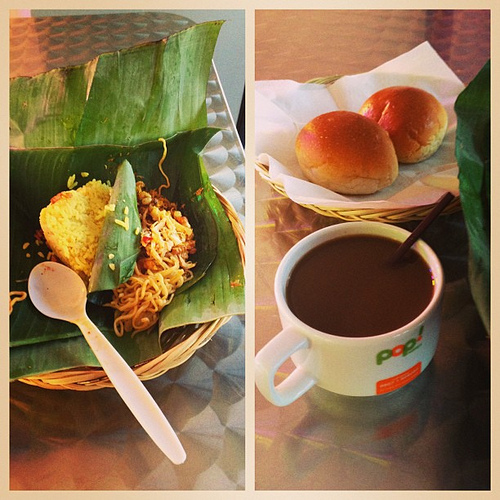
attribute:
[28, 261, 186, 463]
spoon — plastic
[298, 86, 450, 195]
buns — golden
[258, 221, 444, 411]
mug — white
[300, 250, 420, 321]
coffee — brown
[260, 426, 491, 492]
table — silver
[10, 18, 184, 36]
table — patterned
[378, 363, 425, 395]
writing — orange